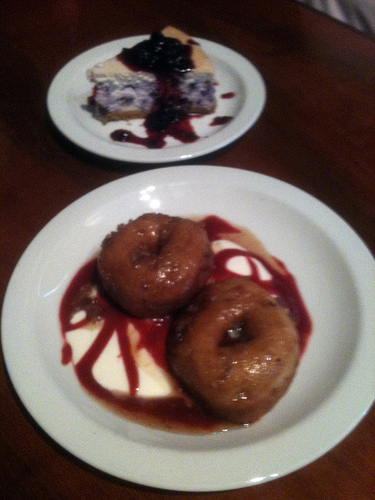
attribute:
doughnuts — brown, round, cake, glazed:
[164, 277, 304, 430]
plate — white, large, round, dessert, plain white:
[3, 164, 375, 495]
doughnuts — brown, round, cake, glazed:
[93, 210, 215, 324]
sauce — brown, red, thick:
[55, 210, 320, 435]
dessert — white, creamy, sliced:
[77, 26, 218, 90]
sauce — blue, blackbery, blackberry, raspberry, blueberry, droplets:
[120, 29, 193, 77]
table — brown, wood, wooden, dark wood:
[1, 1, 375, 500]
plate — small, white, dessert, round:
[43, 26, 271, 167]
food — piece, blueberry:
[86, 73, 224, 128]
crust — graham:
[163, 23, 212, 84]